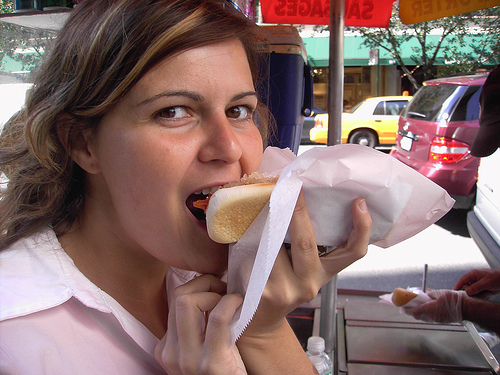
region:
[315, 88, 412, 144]
Yellow cab in the street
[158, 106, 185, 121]
Hazel eye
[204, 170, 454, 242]
Hot dog with onions on it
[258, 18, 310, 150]
Blue and white cooler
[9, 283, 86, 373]
A small part of the lady's white shirt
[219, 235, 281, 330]
White napkin that covers the hot dog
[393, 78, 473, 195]
Back of a red van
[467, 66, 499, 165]
Cap of the person who prepares the hot dog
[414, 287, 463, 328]
Gloves of the hot dog worker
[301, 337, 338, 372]
The top of a bottle of water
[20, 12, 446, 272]
woman eating a hotdog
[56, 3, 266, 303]
woman eating a hotdog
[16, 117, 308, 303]
woman eating a hotdog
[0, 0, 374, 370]
Happy woman with dark blond hair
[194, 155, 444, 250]
paper wrapped hot dog being eaten on street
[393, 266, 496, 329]
hands of street vendor preparing a hot dog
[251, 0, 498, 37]
umbrella covering street vendors cart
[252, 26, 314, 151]
blue cooler with white top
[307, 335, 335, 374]
top of plastic water bottle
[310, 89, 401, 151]
yellow taxi on city street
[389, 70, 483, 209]
back end of maroon suv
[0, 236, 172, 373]
pink collared button down shirt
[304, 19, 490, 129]
shops in background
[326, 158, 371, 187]
part of a paper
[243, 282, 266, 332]
edge of a paper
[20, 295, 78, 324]
edge of a collar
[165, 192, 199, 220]
edge of a mouth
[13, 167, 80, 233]
hair of a lady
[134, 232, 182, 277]
jaw of a lady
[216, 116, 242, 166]
nose of the lady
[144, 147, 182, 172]
cheek of a lady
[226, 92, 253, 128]
eye of a lady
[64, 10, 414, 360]
woman eating a hot dog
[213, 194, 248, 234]
brown tasty bun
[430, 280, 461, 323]
a plastic glove on a hand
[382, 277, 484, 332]
a hand grasping a hot dog bun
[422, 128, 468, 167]
red and white light on a suv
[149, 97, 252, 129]
hazel eyes in a face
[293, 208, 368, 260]
fingers on a hand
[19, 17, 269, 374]
woman wearing a pink top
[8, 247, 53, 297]
white color on pink shirt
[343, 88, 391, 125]
yellow taxi cab in the street